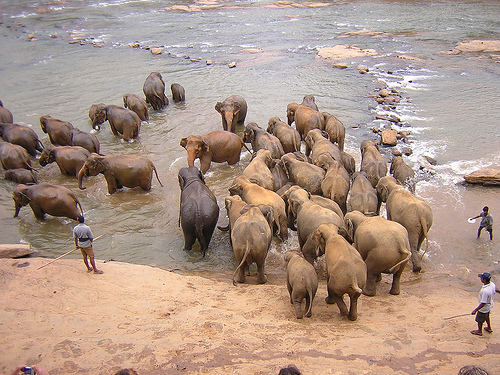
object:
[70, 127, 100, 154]
elephant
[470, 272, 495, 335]
man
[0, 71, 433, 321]
elephants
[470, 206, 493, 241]
kid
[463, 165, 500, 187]
rock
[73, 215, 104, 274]
man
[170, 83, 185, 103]
small elephant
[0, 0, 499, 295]
river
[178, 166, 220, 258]
black elephant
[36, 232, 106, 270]
stick